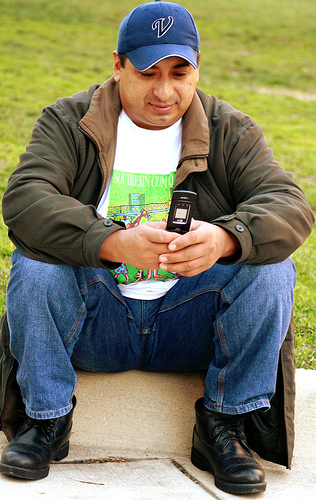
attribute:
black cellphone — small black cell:
[168, 188, 197, 235]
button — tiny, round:
[235, 223, 240, 229]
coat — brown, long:
[0, 74, 315, 470]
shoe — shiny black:
[0, 409, 79, 476]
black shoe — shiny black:
[190, 396, 266, 494]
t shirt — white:
[98, 107, 183, 299]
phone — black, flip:
[156, 181, 196, 275]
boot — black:
[187, 388, 266, 498]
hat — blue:
[116, 1, 201, 71]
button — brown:
[234, 223, 244, 233]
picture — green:
[105, 169, 176, 283]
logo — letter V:
[149, 14, 174, 38]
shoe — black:
[0, 396, 76, 481]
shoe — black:
[190, 395, 266, 495]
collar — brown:
[76, 76, 211, 186]